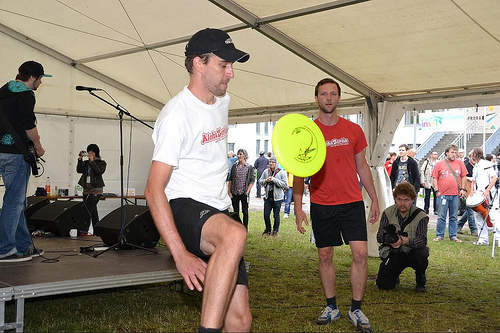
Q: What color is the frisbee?
A: Yellow.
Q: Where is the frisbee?
A: In the air.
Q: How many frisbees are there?
A: One.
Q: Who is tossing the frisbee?
A: The man.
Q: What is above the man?
A: A tent.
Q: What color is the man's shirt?
A: White.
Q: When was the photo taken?
A: Daytime.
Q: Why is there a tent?
A: For protection from the weather.